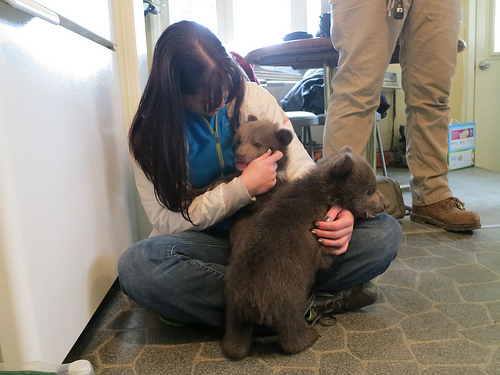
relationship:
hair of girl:
[127, 20, 248, 229] [116, 19, 405, 335]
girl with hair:
[116, 19, 405, 335] [127, 20, 248, 229]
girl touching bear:
[116, 19, 405, 335] [192, 115, 295, 268]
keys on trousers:
[384, 1, 406, 21] [323, 0, 463, 209]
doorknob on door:
[477, 59, 490, 72] [461, 0, 499, 173]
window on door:
[489, 1, 500, 57] [461, 0, 499, 173]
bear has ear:
[217, 143, 391, 360] [331, 153, 356, 178]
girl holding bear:
[116, 19, 405, 335] [217, 143, 391, 360]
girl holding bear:
[116, 19, 405, 335] [192, 115, 295, 268]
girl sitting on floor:
[116, 19, 405, 335] [63, 157, 500, 374]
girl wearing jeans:
[116, 19, 405, 335] [117, 205, 405, 332]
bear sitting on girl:
[192, 115, 295, 268] [116, 19, 405, 335]